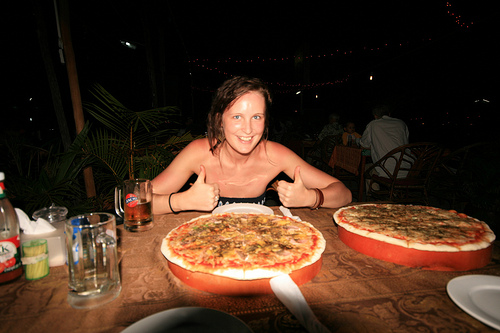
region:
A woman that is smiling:
[132, 75, 351, 208]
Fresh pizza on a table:
[333, 203, 493, 250]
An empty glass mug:
[62, 212, 120, 304]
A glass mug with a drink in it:
[113, 180, 154, 230]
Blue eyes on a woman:
[231, 114, 261, 121]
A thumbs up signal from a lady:
[277, 167, 304, 206]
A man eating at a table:
[358, 104, 414, 177]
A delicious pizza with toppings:
[160, 212, 322, 279]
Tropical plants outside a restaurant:
[2, 85, 187, 210]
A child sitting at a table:
[340, 120, 358, 144]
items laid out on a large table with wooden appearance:
[8, 202, 499, 331]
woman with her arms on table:
[116, 74, 352, 227]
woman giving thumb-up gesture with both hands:
[177, 158, 310, 210]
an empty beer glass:
[65, 211, 123, 307]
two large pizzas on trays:
[161, 198, 498, 297]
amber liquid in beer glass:
[112, 175, 155, 232]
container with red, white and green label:
[0, 162, 21, 276]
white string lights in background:
[166, 1, 488, 91]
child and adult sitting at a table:
[327, 103, 418, 198]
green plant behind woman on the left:
[4, 76, 351, 211]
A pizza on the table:
[159, 206, 327, 286]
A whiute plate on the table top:
[208, 203, 276, 220]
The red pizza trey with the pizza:
[335, 221, 499, 273]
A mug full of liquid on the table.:
[108, 174, 158, 234]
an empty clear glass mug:
[63, 214, 120, 309]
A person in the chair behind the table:
[351, 98, 440, 198]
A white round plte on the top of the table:
[436, 268, 498, 331]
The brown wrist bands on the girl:
[310, 186, 326, 211]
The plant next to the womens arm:
[81, 81, 176, 171]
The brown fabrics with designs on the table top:
[329, 274, 425, 331]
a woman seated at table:
[129, 72, 353, 212]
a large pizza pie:
[161, 210, 328, 279]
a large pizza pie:
[337, 200, 494, 251]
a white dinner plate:
[446, 271, 498, 331]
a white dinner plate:
[121, 305, 248, 331]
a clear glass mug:
[63, 213, 125, 308]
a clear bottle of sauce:
[0, 175, 25, 285]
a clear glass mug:
[113, 179, 155, 232]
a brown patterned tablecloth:
[0, 206, 498, 331]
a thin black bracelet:
[166, 190, 178, 215]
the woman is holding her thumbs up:
[137, 80, 345, 216]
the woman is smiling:
[232, 127, 252, 142]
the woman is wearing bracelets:
[310, 185, 325, 206]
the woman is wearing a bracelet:
[162, 191, 174, 211]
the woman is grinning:
[235, 130, 255, 145]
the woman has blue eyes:
[233, 112, 260, 122]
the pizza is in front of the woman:
[158, 203, 317, 278]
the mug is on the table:
[112, 180, 154, 232]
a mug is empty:
[62, 213, 122, 302]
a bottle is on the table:
[0, 170, 19, 277]